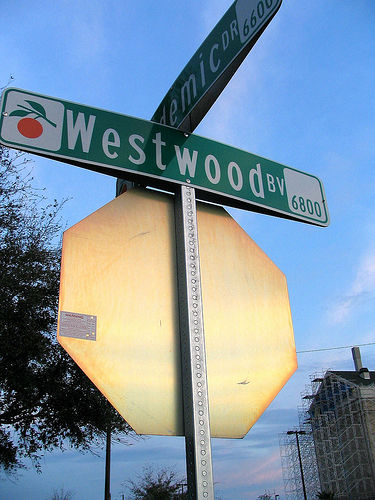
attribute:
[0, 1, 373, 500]
sky — clear, blue, white, streaky, cloudy, in background, partly cloudy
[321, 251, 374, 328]
cloud — white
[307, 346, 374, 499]
building — on right, under construction, tall, in background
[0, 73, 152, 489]
tree — tall, green, large, on left, leafy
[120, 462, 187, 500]
tree — tall, in background, leafy, green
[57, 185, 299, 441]
sign — backside, lined, gold, in foreground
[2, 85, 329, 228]
sign — westwood bv, green, white, in foreground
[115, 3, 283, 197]
sign — green, white, in foreground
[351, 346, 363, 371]
chimney — silver, large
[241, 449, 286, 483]
cloud — slightly red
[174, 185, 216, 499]
pole — metal, steel, grey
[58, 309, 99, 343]
label — tan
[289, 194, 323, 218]
6800 — green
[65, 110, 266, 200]
word — white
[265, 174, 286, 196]
word — white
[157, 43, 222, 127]
word — white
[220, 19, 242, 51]
word — white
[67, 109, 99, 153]
letter — white, w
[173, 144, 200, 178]
letter — white, w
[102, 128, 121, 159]
letter — white, e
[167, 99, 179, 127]
letter — white, e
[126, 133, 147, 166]
letter — white, s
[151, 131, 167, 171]
letter — white, t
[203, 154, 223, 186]
letter — white, o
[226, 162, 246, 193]
letter — o, white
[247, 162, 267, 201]
letter — d, white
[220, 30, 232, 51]
letter — d, white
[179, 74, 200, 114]
letter — m, white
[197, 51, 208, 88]
letter — i, white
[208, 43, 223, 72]
letter — c, white